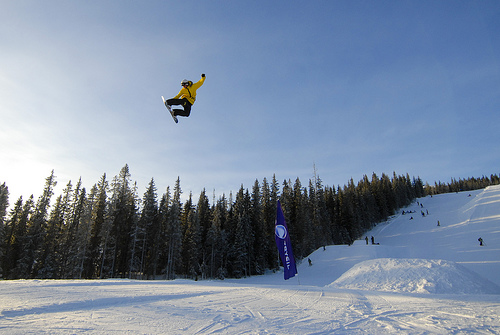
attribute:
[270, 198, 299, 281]
flag — purple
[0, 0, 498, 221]
sky — blue 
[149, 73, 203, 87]
helmet — white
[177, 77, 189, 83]
helmet — white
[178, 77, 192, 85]
helmet — white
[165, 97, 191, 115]
pants — black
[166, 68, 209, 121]
snowboard — white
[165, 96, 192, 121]
pants — black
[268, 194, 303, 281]
sign — blue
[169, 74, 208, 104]
jacket — yellow